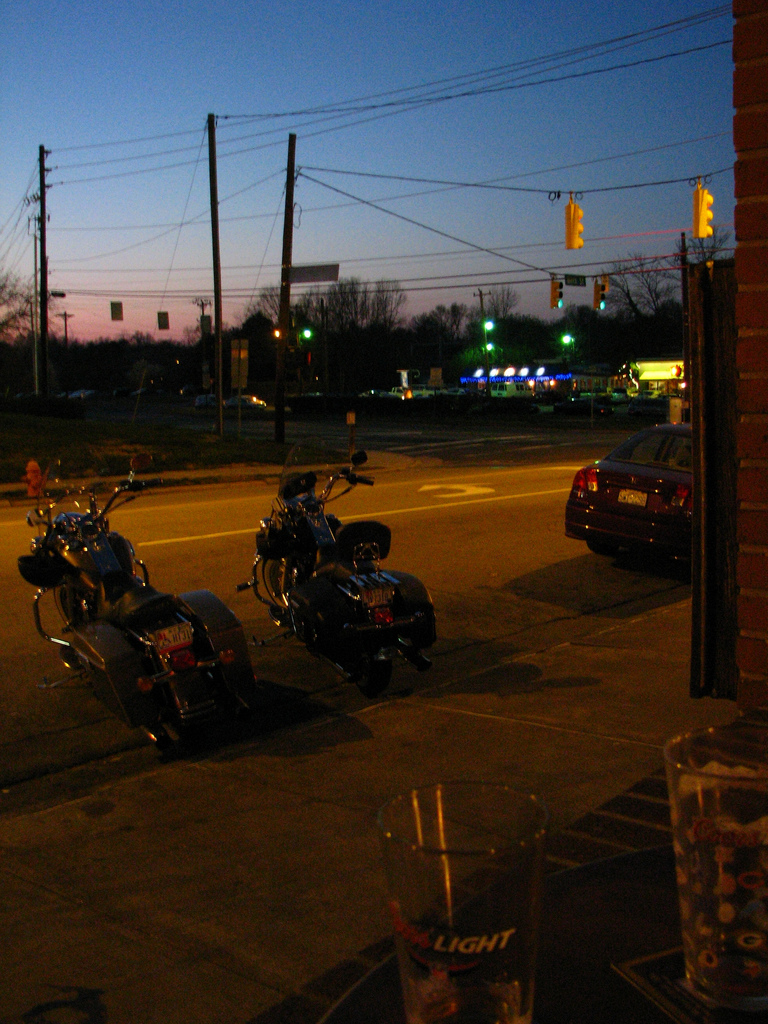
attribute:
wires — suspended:
[4, 5, 765, 317]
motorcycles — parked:
[14, 438, 445, 750]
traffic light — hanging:
[684, 178, 720, 240]